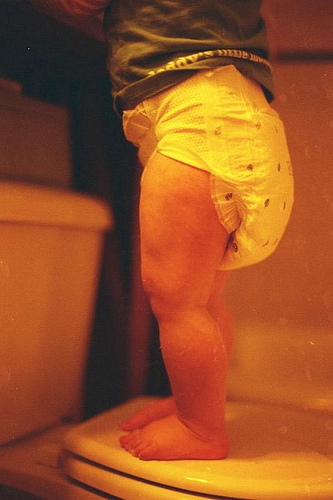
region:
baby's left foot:
[117, 407, 232, 463]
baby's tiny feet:
[110, 389, 244, 467]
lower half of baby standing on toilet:
[37, 0, 331, 477]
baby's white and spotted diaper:
[121, 58, 305, 268]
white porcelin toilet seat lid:
[61, 395, 332, 495]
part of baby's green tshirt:
[106, 0, 293, 104]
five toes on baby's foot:
[113, 430, 152, 465]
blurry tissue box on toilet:
[1, 75, 82, 184]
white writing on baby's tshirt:
[138, 43, 280, 76]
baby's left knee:
[131, 261, 219, 338]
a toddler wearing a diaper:
[107, 62, 303, 281]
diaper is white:
[114, 62, 305, 276]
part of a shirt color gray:
[94, 1, 291, 111]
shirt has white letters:
[99, 7, 278, 101]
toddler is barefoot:
[80, 5, 302, 470]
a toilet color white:
[4, 175, 328, 498]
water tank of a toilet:
[0, 168, 116, 434]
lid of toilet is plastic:
[58, 384, 332, 497]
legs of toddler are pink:
[111, 149, 253, 465]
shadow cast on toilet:
[224, 380, 331, 484]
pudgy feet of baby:
[117, 397, 228, 457]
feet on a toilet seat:
[106, 336, 254, 497]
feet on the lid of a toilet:
[114, 322, 249, 478]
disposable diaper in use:
[115, 63, 299, 269]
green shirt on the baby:
[86, 0, 277, 107]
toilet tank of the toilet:
[0, 179, 115, 436]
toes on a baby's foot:
[115, 424, 153, 463]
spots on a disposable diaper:
[243, 111, 297, 253]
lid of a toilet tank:
[0, 180, 111, 230]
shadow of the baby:
[230, 416, 327, 464]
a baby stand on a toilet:
[49, 0, 301, 467]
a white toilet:
[0, 185, 326, 495]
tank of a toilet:
[1, 170, 116, 449]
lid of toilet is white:
[4, 170, 115, 255]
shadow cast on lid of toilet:
[233, 393, 331, 498]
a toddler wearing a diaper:
[90, 3, 302, 470]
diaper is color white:
[121, 67, 303, 279]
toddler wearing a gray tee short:
[85, 5, 284, 109]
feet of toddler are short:
[105, 150, 245, 469]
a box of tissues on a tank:
[0, 66, 117, 249]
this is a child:
[96, 2, 304, 469]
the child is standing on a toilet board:
[65, 399, 328, 497]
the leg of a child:
[116, 182, 233, 455]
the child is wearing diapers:
[103, 68, 304, 267]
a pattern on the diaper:
[259, 196, 272, 208]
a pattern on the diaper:
[222, 188, 239, 207]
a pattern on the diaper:
[270, 157, 283, 180]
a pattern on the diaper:
[280, 198, 289, 213]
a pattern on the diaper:
[259, 235, 273, 249]